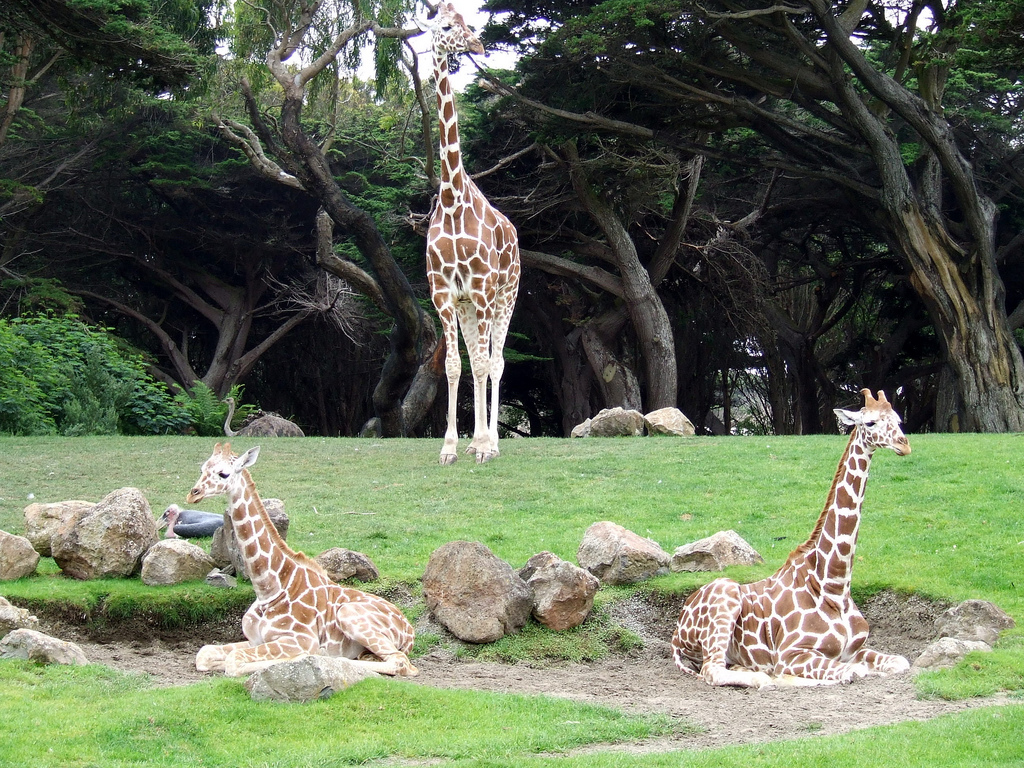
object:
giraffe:
[421, 4, 525, 466]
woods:
[0, 0, 1021, 438]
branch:
[570, 173, 690, 415]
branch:
[810, 5, 1005, 317]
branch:
[87, 5, 412, 437]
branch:
[647, 117, 708, 278]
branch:
[462, 74, 683, 156]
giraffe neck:
[210, 482, 298, 582]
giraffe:
[181, 440, 417, 677]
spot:
[465, 217, 479, 232]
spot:
[465, 219, 484, 252]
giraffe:
[670, 388, 914, 690]